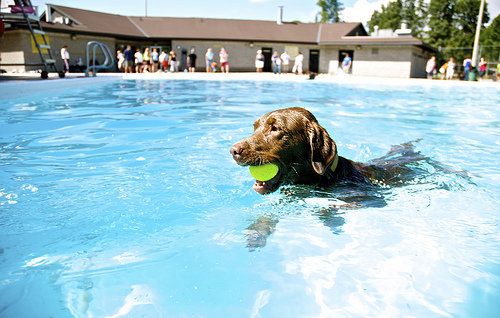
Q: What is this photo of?
A: Pool.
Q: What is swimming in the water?
A: Brown dog.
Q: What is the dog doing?
A: Swimming.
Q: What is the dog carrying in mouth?
A: A ball.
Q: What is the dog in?
A: A swimming pool.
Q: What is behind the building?
A: Trees.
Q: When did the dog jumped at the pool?
A: Earlier.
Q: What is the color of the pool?
A: Blue.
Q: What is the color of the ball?
A: Green.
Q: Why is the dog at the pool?
A: To swim.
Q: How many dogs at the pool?
A: One.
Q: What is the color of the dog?
A: Brown.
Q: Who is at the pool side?
A: Crowd.